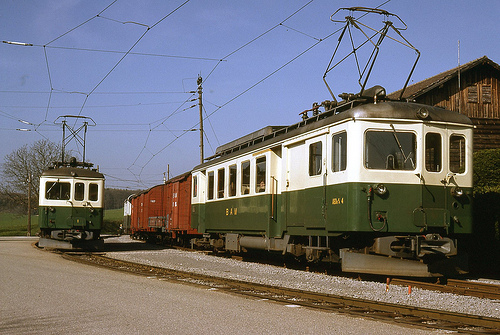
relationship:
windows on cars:
[217, 156, 283, 186] [197, 137, 388, 225]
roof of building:
[403, 68, 454, 95] [425, 68, 490, 101]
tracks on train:
[261, 283, 381, 325] [53, 163, 316, 232]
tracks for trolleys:
[261, 283, 381, 325] [128, 158, 300, 234]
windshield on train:
[364, 122, 414, 167] [53, 163, 316, 232]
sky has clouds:
[145, 25, 247, 117] [138, 126, 182, 178]